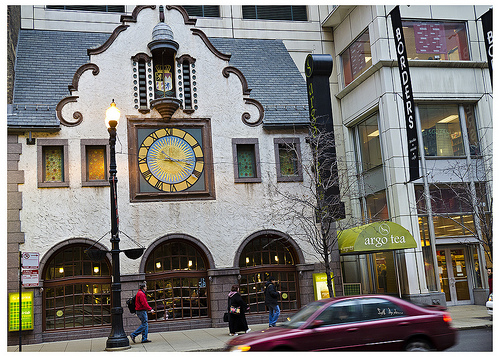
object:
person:
[220, 283, 249, 336]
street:
[99, 312, 491, 351]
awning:
[333, 219, 417, 256]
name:
[364, 232, 410, 247]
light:
[104, 101, 120, 127]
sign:
[23, 252, 40, 289]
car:
[227, 294, 461, 352]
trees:
[409, 116, 489, 326]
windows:
[400, 23, 465, 61]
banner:
[388, 5, 424, 186]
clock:
[131, 119, 215, 201]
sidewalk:
[6, 293, 485, 355]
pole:
[106, 102, 131, 348]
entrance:
[339, 250, 372, 302]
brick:
[343, 282, 363, 303]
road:
[222, 323, 489, 352]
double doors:
[438, 251, 472, 305]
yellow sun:
[146, 133, 190, 183]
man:
[128, 282, 156, 343]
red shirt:
[134, 289, 150, 309]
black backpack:
[126, 298, 138, 314]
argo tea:
[363, 236, 405, 248]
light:
[435, 223, 459, 230]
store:
[363, 186, 499, 316]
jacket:
[133, 293, 159, 313]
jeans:
[129, 311, 151, 343]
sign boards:
[314, 271, 338, 303]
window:
[40, 142, 66, 185]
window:
[83, 142, 104, 184]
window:
[234, 140, 255, 180]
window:
[278, 140, 300, 177]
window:
[333, 24, 370, 92]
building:
[4, 1, 340, 344]